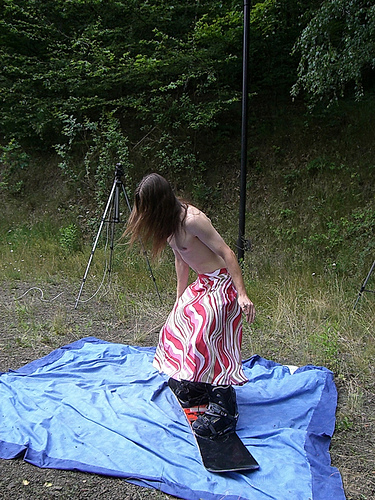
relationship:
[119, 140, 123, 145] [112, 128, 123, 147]
leaf on stem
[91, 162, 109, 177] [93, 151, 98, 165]
leaf on stem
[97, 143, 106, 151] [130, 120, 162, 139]
leaf on stem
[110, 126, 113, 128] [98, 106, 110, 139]
leaf on stem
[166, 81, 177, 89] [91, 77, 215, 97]
leaf on stem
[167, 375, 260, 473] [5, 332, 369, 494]
snowboard on blanket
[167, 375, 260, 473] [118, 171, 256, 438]
snowboard under man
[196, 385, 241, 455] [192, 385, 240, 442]
boot on boot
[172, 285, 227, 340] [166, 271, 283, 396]
skirt on half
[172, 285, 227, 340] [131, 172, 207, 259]
skirt on man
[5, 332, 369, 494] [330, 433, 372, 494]
blanket on ground